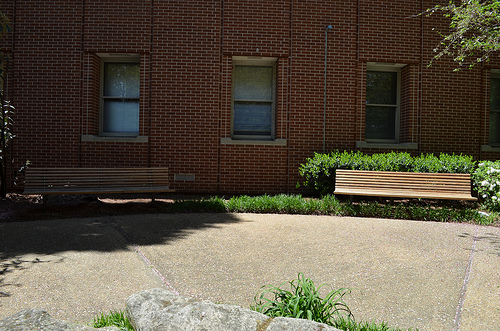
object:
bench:
[21, 167, 176, 210]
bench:
[332, 169, 478, 207]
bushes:
[296, 148, 366, 197]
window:
[99, 57, 142, 137]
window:
[231, 60, 277, 139]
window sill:
[81, 133, 149, 143]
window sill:
[220, 137, 287, 147]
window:
[364, 67, 402, 142]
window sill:
[356, 140, 419, 149]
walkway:
[2, 212, 498, 331]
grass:
[165, 193, 500, 227]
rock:
[128, 287, 347, 331]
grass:
[328, 314, 394, 330]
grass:
[161, 281, 208, 306]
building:
[1, 1, 497, 195]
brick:
[176, 93, 186, 97]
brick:
[294, 115, 305, 118]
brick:
[335, 56, 344, 59]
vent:
[174, 173, 196, 182]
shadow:
[0, 189, 254, 296]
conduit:
[321, 24, 333, 154]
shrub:
[421, 153, 474, 172]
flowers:
[481, 179, 491, 187]